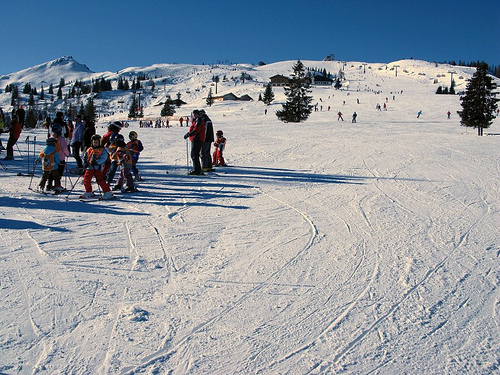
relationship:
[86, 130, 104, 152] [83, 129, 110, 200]
head of child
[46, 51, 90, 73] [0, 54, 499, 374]
peak of snow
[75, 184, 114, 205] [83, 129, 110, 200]
boots on child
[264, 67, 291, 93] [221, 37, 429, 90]
house in distance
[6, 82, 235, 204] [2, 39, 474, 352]
children in photo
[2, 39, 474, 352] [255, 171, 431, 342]
place full snow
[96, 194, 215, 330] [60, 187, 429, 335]
lines on ground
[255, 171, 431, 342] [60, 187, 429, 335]
snow on ground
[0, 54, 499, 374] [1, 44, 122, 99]
snow covered hill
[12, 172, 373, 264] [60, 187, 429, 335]
shadow on ground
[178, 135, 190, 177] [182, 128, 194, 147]
poles in hand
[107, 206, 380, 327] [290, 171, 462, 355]
markings in snow